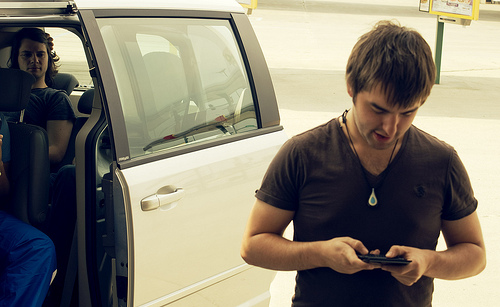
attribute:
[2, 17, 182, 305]
door — open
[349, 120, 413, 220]
necklace — silver, blue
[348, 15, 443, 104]
hair — long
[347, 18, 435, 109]
hair — brown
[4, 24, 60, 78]
hair — brown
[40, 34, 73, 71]
hair — shoulder length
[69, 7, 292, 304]
sliding door — open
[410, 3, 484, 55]
objects — yellow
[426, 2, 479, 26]
object — Yellow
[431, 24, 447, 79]
post — green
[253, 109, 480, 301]
shirt — short sleeve, brown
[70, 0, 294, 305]
door — open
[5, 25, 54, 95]
man van — young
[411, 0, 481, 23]
sign — green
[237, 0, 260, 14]
sign —  yellow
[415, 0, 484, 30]
sign —  yellow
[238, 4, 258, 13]
object — yellow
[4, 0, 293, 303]
car — open